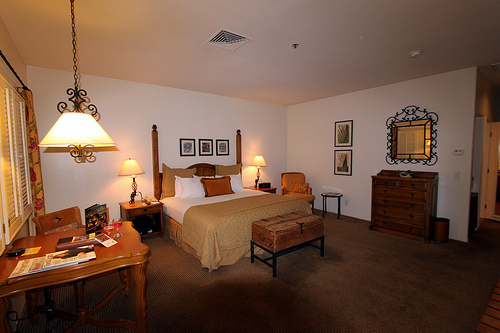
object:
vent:
[207, 30, 248, 51]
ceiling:
[83, 1, 336, 94]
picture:
[333, 120, 354, 148]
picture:
[334, 151, 354, 176]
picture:
[218, 138, 231, 156]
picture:
[199, 139, 213, 156]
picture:
[179, 139, 194, 157]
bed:
[153, 161, 311, 254]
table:
[321, 191, 344, 217]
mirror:
[389, 121, 429, 157]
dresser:
[369, 169, 440, 239]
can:
[431, 217, 450, 244]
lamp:
[250, 154, 270, 185]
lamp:
[117, 157, 149, 200]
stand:
[123, 202, 164, 238]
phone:
[144, 195, 158, 204]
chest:
[246, 210, 328, 266]